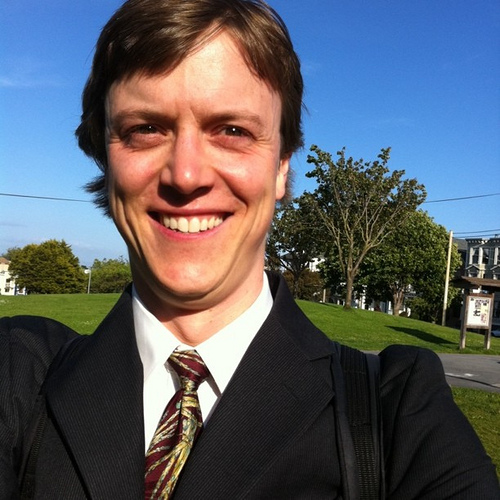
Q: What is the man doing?
A: Smiling.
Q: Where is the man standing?
A: Park.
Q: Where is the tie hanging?
A: Neck.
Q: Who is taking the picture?
A: The man.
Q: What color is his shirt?
A: White.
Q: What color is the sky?
A: Blue.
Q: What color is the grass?
A: Green.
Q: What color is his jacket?
A: Black.